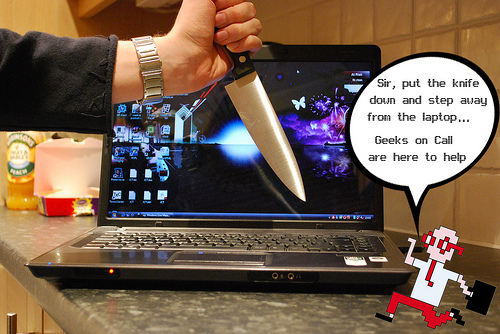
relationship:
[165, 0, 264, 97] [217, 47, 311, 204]
hand holding knife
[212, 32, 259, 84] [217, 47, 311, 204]
handle on knife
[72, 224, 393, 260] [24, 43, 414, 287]
keyboard on laptop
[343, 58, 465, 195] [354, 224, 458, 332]
quote coming from man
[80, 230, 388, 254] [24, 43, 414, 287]
keyboard on laptop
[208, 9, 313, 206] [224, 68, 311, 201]
knife has blade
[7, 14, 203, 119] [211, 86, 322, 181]
person holding knife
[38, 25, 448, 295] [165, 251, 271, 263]
computer has touch-pad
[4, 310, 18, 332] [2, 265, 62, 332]
handle on cabinet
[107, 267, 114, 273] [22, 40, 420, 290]
power light on computer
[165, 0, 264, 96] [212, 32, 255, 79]
hand gripping handle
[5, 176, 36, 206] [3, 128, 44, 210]
peach juice in bottle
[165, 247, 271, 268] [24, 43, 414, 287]
touch-pad on laptop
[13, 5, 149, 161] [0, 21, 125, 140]
sleeve on jacket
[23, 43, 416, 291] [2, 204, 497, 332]
computer on counter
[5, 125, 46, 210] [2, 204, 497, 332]
bottle on counter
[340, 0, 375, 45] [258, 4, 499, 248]
tile on wall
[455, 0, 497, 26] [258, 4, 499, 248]
tile on wall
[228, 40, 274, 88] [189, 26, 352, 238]
bolt on knife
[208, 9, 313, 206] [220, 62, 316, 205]
knife raised blade